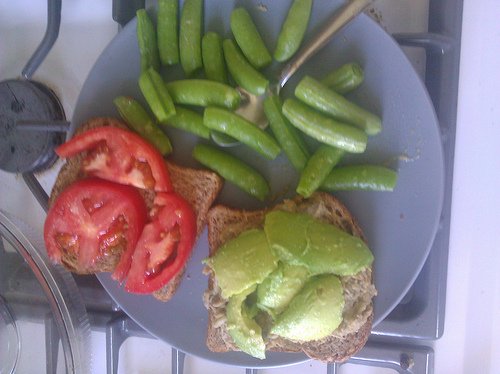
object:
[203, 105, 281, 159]
greenbean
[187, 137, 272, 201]
green bean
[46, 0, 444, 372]
plate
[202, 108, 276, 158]
greens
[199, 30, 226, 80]
green bean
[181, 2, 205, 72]
green bean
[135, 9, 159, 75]
bean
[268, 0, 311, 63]
green beans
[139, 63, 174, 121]
greens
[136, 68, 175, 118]
green bean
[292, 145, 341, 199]
green bean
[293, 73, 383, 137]
green bean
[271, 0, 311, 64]
green bean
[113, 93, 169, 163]
greens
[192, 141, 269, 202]
green bean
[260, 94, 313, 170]
green bean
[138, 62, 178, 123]
green bean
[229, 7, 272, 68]
green bean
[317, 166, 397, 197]
green bean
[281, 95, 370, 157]
greens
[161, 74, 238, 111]
greens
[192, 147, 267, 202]
greens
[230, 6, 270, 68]
greens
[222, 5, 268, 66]
greens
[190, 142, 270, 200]
greens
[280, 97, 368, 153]
greens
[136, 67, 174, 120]
greens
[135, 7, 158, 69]
greens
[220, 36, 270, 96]
green bean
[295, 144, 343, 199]
bean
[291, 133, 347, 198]
green beans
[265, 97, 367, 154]
green bean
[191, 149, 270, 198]
greens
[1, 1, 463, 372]
burner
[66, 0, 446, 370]
dish